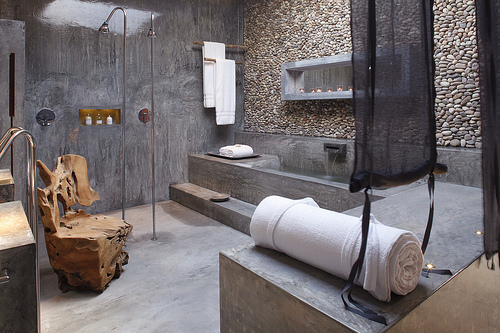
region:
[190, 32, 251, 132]
bath towels hanging on rack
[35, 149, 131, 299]
tan clay chair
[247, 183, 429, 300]
white rolled up towel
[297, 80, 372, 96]
lit candles on the shelf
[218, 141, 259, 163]
bath towel beside tub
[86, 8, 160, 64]
two silver shower heads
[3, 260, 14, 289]
silver handle of the cupboard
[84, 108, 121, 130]
bottles on the shelf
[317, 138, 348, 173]
water coming out of the spout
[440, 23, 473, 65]
small pebbles wall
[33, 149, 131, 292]
chair sculpted out of wood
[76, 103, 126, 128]
a shelf of toiletries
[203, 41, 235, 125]
towels on two hangers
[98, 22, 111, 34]
shower head high above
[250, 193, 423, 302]
a rolled up mat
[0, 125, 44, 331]
bars for entry on the left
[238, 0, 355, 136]
rounded stones on the wall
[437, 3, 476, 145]
a wall of river rocks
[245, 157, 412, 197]
a unique bath rub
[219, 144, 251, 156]
folded towel by the bath tub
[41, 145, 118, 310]
a chair made of wood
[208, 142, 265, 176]
a folded towel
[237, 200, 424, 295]
a blanket rolled up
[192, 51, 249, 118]
a towel on a wood rod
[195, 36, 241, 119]
two towels hanging on a rod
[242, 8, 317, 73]
a rock wall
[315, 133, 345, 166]
a water faucet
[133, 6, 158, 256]
a tall shower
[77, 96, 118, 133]
two white bottles on a shelf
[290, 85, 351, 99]
a row of candles on a shelf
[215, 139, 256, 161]
a folded white towel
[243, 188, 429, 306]
a rolled white towel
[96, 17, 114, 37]
a light on the pole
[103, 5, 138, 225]
a gray metal pole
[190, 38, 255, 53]
a wooden towel rack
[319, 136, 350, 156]
a water spout in the wall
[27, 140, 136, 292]
a brown wooden chair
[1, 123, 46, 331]
gray metal railing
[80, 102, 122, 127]
bottles on the wall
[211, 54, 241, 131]
a towel on the rack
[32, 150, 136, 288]
Large wooden chair with many holes and twists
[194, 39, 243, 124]
Two white towels hanging together on a wall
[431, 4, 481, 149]
Wall of small light gray pebbles and stones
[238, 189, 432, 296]
Folded up white towel lying on a counter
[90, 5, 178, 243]
Tall gray metal shower head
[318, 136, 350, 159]
Small gray metal box against a gray wall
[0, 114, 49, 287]
Two metal support bars near a counter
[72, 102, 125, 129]
Row of white bottles of shower products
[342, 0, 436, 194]
Dark colored see through cloth hanging from above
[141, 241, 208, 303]
Light gray stone floor of a bathroom